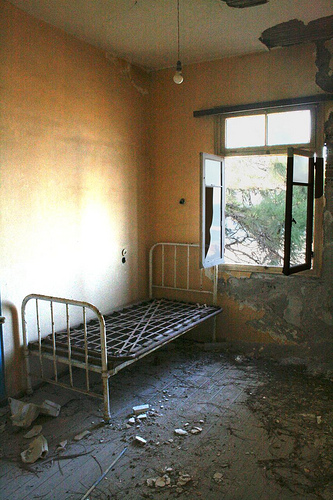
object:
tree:
[221, 188, 308, 265]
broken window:
[200, 154, 224, 264]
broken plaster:
[134, 432, 148, 446]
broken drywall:
[220, 272, 332, 346]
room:
[0, 0, 333, 500]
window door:
[282, 148, 314, 276]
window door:
[198, 152, 225, 267]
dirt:
[246, 361, 320, 433]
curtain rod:
[193, 94, 332, 118]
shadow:
[127, 226, 150, 303]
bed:
[21, 238, 223, 418]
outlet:
[122, 249, 127, 256]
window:
[193, 95, 326, 276]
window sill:
[214, 264, 315, 277]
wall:
[149, 37, 333, 356]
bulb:
[173, 60, 184, 84]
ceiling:
[0, 0, 330, 73]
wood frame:
[199, 152, 224, 268]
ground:
[1, 342, 333, 500]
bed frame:
[20, 240, 222, 422]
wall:
[0, 3, 157, 405]